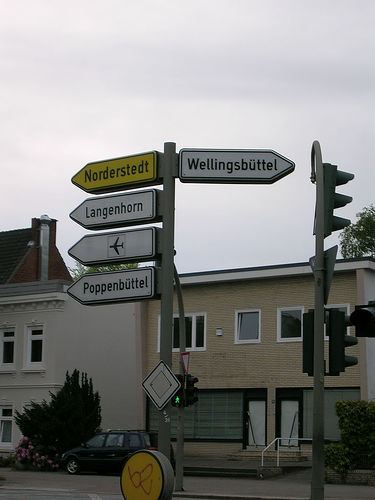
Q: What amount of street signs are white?
A: Four.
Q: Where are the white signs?
A: On pole.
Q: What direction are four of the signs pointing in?
A: The left.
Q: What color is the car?
A: Black.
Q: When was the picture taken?
A: During the day.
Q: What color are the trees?
A: Green.